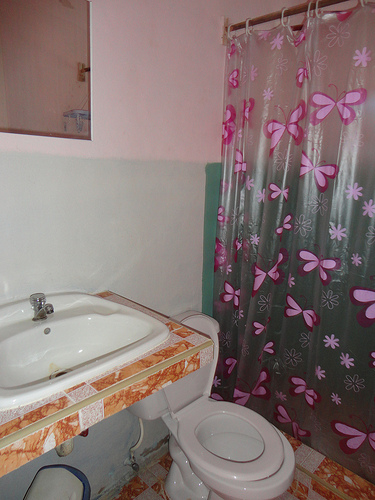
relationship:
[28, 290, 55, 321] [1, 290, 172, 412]
faucet of sink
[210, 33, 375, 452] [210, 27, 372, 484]
butterfly on curtain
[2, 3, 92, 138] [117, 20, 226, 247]
panel on wall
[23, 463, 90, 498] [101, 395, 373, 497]
trash can on floor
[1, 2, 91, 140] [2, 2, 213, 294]
mirror on wall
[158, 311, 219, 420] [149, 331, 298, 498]
lid on toilet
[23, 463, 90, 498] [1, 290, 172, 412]
trash can below sink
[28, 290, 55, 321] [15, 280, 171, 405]
faucet over sink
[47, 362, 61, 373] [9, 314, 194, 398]
stain on sink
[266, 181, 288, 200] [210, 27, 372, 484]
butterfly on curtain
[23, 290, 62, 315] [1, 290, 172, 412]
faucet on sink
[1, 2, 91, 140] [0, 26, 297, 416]
mirror on wall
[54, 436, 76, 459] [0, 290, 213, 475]
pipe under sink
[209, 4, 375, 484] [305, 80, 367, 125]
curtain with butterfly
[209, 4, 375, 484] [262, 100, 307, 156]
curtain with butterfly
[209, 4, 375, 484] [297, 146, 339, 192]
curtain with butterfly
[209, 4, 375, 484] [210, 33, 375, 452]
curtain with butterfly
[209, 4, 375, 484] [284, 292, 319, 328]
curtain with butterfly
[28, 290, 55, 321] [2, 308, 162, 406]
faucet on sink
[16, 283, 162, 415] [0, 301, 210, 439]
sink on counter top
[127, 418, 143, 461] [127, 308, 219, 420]
pipe leading to toilet tank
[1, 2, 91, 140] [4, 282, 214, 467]
mirror above sink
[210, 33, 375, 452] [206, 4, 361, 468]
butterfly on curtain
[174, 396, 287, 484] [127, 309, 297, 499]
seat of toilet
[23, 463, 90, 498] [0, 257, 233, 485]
trash can under sink